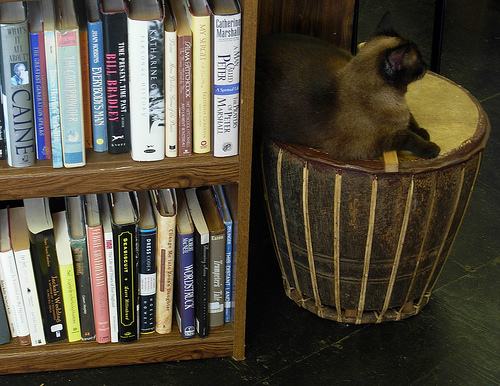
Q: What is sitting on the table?
A: Cat.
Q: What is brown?
A: Bookcase.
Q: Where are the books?
A: On the shelves.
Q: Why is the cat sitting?
A: Resting.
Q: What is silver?
A: CAINE the book.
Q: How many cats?
A: One.